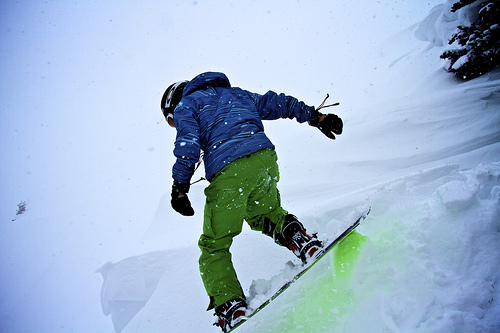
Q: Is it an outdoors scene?
A: Yes, it is outdoors.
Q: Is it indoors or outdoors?
A: It is outdoors.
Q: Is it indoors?
A: No, it is outdoors.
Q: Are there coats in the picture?
A: Yes, there is a coat.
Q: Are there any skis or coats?
A: Yes, there is a coat.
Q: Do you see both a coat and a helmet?
A: Yes, there are both a coat and a helmet.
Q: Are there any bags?
A: No, there are no bags.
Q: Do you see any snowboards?
A: Yes, there is a snowboard.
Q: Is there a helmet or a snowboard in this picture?
A: Yes, there is a snowboard.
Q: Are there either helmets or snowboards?
A: Yes, there is a snowboard.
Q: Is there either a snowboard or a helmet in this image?
A: Yes, there is a snowboard.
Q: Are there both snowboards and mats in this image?
A: No, there is a snowboard but no mats.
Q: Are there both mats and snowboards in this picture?
A: No, there is a snowboard but no mats.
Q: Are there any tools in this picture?
A: No, there are no tools.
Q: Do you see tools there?
A: No, there are no tools.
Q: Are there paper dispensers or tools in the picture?
A: No, there are no tools or paper dispensers.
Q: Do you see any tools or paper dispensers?
A: No, there are no tools or paper dispensers.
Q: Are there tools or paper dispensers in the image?
A: No, there are no tools or paper dispensers.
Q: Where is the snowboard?
A: The snowboard is on the snow.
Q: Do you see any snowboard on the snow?
A: Yes, there is a snowboard on the snow.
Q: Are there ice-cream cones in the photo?
A: No, there are no ice-cream cones.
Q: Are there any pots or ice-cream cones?
A: No, there are no ice-cream cones or pots.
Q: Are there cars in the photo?
A: No, there are no cars.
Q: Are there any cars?
A: No, there are no cars.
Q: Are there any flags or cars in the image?
A: No, there are no cars or flags.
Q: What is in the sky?
A: The clouds are in the sky.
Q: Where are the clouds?
A: The clouds are in the sky.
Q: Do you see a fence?
A: No, there are no fences.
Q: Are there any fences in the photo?
A: No, there are no fences.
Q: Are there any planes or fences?
A: No, there are no fences or planes.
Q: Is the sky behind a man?
A: Yes, the sky is behind a man.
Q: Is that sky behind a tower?
A: No, the sky is behind a man.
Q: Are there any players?
A: No, there are no players.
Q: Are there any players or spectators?
A: No, there are no players or spectators.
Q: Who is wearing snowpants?
A: The man is wearing snowpants.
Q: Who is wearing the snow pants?
A: The man is wearing snowpants.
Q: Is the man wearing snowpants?
A: Yes, the man is wearing snowpants.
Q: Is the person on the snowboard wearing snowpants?
A: Yes, the man is wearing snowpants.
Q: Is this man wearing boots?
A: No, the man is wearing snowpants.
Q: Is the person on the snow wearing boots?
A: No, the man is wearing snowpants.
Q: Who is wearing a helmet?
A: The man is wearing a helmet.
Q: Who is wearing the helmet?
A: The man is wearing a helmet.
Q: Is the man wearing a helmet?
A: Yes, the man is wearing a helmet.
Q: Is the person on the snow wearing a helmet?
A: Yes, the man is wearing a helmet.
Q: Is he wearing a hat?
A: No, the man is wearing a helmet.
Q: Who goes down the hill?
A: The man goes down the hill.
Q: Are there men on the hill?
A: Yes, there is a man on the hill.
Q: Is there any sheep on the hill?
A: No, there is a man on the hill.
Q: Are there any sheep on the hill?
A: No, there is a man on the hill.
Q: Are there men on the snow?
A: Yes, there is a man on the snow.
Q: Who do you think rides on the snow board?
A: The man rides on the snow board.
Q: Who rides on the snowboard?
A: The man rides on the snow board.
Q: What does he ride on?
A: The man rides on the snowboard.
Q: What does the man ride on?
A: The man rides on the snowboard.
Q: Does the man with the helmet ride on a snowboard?
A: Yes, the man rides on a snowboard.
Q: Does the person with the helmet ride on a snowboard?
A: Yes, the man rides on a snowboard.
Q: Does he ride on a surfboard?
A: No, the man rides on a snowboard.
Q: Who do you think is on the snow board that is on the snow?
A: The man is on the snow board.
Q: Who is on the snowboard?
A: The man is on the snow board.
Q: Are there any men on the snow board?
A: Yes, there is a man on the snow board.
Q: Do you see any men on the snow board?
A: Yes, there is a man on the snow board.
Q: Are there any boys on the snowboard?
A: No, there is a man on the snowboard.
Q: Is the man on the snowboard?
A: Yes, the man is on the snowboard.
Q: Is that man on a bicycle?
A: No, the man is on the snowboard.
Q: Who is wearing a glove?
A: The man is wearing a glove.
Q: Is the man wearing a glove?
A: Yes, the man is wearing a glove.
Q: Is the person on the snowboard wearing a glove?
A: Yes, the man is wearing a glove.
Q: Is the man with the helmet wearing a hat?
A: No, the man is wearing a glove.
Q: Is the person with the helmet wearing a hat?
A: No, the man is wearing a glove.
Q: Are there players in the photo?
A: No, there are no players.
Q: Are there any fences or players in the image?
A: No, there are no players or fences.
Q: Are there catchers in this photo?
A: No, there are no catchers.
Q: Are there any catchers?
A: No, there are no catchers.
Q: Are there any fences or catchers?
A: No, there are no catchers or fences.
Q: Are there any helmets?
A: Yes, there is a helmet.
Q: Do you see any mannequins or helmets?
A: Yes, there is a helmet.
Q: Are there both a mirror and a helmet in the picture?
A: No, there is a helmet but no mirrors.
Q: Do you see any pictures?
A: No, there are no pictures.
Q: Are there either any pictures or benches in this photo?
A: No, there are no pictures or benches.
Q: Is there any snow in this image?
A: Yes, there is snow.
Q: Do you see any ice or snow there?
A: Yes, there is snow.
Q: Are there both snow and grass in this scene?
A: No, there is snow but no grass.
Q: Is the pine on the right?
A: Yes, the pine is on the right of the image.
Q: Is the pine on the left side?
A: No, the pine is on the right of the image.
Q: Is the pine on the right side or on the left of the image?
A: The pine is on the right of the image.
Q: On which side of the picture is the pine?
A: The pine is on the right of the image.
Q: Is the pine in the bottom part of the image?
A: No, the pine is in the top of the image.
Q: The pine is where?
A: The pine is on the hill.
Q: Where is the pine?
A: The pine is on the hill.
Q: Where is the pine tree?
A: The pine is on the hill.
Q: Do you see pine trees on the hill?
A: Yes, there is a pine tree on the hill.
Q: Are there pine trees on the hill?
A: Yes, there is a pine tree on the hill.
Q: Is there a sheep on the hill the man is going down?
A: No, there is a pine tree on the hill.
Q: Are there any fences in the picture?
A: No, there are no fences.